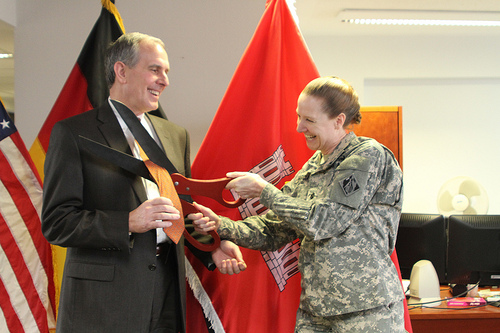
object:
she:
[188, 75, 408, 332]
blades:
[77, 134, 156, 184]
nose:
[296, 121, 312, 132]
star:
[0, 117, 11, 128]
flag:
[0, 99, 58, 332]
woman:
[182, 75, 187, 209]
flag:
[186, 0, 413, 331]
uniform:
[217, 131, 406, 332]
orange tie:
[137, 139, 185, 245]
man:
[41, 32, 248, 331]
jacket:
[42, 100, 215, 332]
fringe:
[183, 254, 225, 331]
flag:
[30, 1, 171, 332]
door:
[339, 107, 402, 173]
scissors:
[77, 98, 247, 251]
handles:
[170, 173, 248, 208]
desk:
[402, 284, 499, 332]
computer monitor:
[393, 212, 448, 284]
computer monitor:
[447, 213, 500, 272]